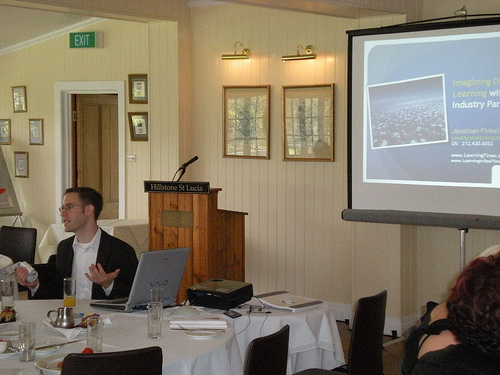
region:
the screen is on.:
[340, 10, 498, 230]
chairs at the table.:
[50, 280, 395, 373]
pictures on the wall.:
[214, 74, 340, 169]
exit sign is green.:
[64, 25, 106, 55]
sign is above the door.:
[57, 25, 106, 58]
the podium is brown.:
[140, 148, 252, 294]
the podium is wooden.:
[134, 150, 252, 290]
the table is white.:
[0, 276, 357, 373]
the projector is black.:
[182, 267, 255, 312]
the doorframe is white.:
[47, 73, 137, 234]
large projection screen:
[346, 19, 498, 229]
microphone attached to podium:
[141, 153, 246, 299]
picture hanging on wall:
[221, 82, 271, 161]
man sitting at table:
[11, 186, 137, 305]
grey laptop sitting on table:
[89, 250, 187, 310]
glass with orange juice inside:
[63, 278, 75, 309]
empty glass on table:
[18, 323, 35, 362]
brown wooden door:
[63, 92, 120, 230]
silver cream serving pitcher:
[48, 306, 77, 328]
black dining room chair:
[306, 293, 385, 373]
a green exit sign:
[49, 23, 116, 60]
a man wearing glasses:
[21, 183, 123, 302]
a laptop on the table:
[80, 252, 197, 321]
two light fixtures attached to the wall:
[206, 22, 341, 82]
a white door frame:
[30, 70, 143, 193]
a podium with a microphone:
[134, 146, 244, 256]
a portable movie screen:
[328, 8, 498, 249]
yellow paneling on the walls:
[248, 170, 345, 292]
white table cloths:
[225, 297, 352, 374]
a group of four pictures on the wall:
[0, 76, 47, 185]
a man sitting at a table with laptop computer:
[12, 185, 192, 311]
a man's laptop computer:
[91, 247, 191, 319]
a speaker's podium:
[141, 152, 256, 279]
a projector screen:
[340, 6, 498, 250]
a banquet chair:
[313, 294, 388, 374]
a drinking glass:
[148, 300, 163, 342]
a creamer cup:
[46, 302, 76, 330]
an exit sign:
[66, 31, 96, 48]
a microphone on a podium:
[170, 151, 198, 178]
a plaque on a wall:
[223, 84, 271, 160]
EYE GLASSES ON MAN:
[51, 200, 87, 211]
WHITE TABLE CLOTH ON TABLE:
[11, 293, 329, 373]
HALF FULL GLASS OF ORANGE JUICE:
[61, 275, 85, 300]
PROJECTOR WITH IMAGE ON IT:
[351, 32, 497, 199]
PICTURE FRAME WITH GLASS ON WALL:
[209, 83, 274, 160]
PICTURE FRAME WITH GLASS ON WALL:
[281, 76, 338, 161]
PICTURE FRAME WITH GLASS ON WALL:
[7, 87, 29, 112]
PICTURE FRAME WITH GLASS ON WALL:
[28, 120, 50, 145]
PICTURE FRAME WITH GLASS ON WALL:
[14, 151, 36, 175]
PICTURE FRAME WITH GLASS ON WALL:
[123, 114, 153, 147]